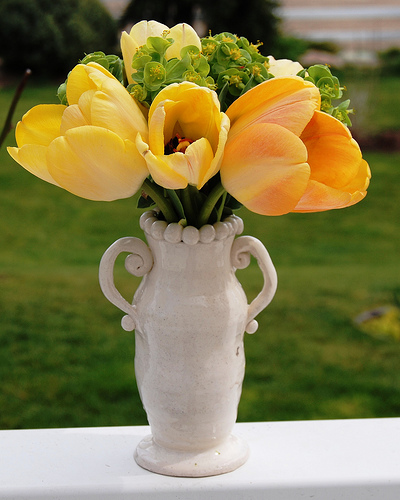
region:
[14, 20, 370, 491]
tulips in a vase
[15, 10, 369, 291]
there are five tulips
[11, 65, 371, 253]
the tulips are open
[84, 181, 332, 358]
the vase is ceramic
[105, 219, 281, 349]
the vase has two handles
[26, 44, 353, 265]
the tulips are yellow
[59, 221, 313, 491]
the vase is white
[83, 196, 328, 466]
the vase is outside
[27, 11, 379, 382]
the flowers are outside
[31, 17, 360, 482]
tulips in a bouquet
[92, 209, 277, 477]
white vase on the edge.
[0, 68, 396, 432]
Grass in the background.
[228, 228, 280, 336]
Handle on the vase.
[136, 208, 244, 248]
White balls on the rim of the vase.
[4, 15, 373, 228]
bouquet of flowers in the vase.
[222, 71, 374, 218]
Yellow tulip in the bouquet.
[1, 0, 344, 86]
Hedges in the background.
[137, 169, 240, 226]
Green stems on the flowers.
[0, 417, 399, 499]
White ledge in the forefront.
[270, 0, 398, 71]
House in the background.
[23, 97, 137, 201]
yellow flower in white vase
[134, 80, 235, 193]
yellow flower in white vase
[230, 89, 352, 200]
yellow flower in white vase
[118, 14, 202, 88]
yellow flower in white vase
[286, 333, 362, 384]
green grass in background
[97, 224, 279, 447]
white vase on white rail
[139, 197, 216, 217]
green stems of flowers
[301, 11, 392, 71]
wall in background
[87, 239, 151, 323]
small handle of white vase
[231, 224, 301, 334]
small handle of white vase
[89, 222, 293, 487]
A small white vase.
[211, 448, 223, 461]
A round imperfection in the base.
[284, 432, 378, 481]
This window seal is white.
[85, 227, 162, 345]
The left handle of the vase.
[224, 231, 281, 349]
This is the right handle of the vase.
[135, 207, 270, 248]
The opening of the vase has a design that resembles pearls.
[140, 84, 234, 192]
A small yellow flower.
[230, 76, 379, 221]
A large yellow flower on the right.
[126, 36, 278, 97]
Green flowers with yellow centers.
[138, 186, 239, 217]
The green stems of the flowers.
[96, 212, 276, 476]
a white ceramic vase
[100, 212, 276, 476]
a white vase with two handles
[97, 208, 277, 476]
a white vase with decorative opening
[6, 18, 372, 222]
bouquet of yellow tulips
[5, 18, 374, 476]
yellow tulips in a white vase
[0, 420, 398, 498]
what the vase is sitting on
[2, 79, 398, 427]
grassy area behind the vase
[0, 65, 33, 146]
a brown twig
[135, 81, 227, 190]
most open tulip viewable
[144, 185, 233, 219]
stems of the tulip